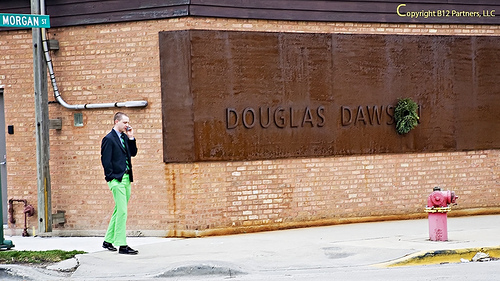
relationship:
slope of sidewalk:
[163, 253, 236, 279] [204, 192, 401, 277]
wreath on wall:
[391, 97, 420, 133] [161, 30, 498, 227]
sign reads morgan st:
[0, 12, 50, 29] [2, 14, 47, 24]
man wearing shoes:
[100, 112, 141, 260] [98, 238, 143, 254]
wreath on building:
[391, 97, 420, 133] [191, 36, 494, 221]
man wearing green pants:
[91, 104, 142, 258] [104, 171, 134, 245]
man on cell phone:
[91, 104, 142, 258] [112, 113, 150, 137]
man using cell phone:
[100, 112, 141, 260] [125, 125, 138, 136]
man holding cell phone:
[100, 112, 141, 260] [125, 121, 132, 132]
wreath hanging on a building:
[391, 97, 422, 135] [4, 3, 499, 235]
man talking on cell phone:
[91, 104, 142, 258] [125, 127, 131, 131]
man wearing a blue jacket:
[100, 112, 141, 260] [98, 126, 138, 182]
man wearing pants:
[100, 112, 141, 260] [102, 171, 130, 245]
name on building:
[224, 104, 398, 126] [4, 3, 499, 235]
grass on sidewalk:
[6, 242, 44, 260] [45, 225, 172, 279]